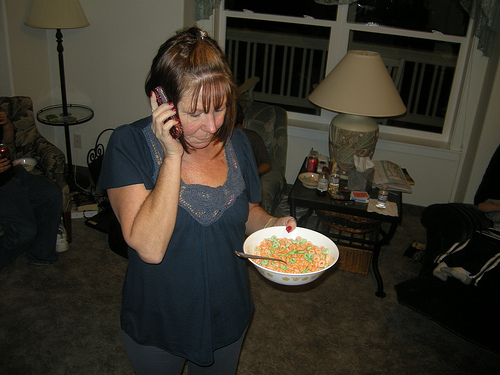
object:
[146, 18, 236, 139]
hair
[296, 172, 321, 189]
bowl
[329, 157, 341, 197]
water bottle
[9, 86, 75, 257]
chair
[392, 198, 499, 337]
chair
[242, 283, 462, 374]
carpet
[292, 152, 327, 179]
can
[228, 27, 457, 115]
wooden fence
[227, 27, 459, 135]
white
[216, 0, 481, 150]
window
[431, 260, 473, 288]
white sock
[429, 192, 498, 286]
boy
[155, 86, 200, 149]
phone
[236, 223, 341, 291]
bowl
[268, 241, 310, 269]
cereal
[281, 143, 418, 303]
stand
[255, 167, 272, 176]
arm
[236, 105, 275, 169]
man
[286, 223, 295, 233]
nail polish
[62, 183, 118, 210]
book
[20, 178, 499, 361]
floor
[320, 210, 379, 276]
basket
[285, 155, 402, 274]
table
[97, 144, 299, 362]
shirt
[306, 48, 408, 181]
lamp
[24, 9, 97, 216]
floor lamp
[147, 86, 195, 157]
hand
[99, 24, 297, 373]
woman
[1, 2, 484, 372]
home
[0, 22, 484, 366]
foreground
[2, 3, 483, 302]
background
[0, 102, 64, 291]
person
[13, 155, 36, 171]
cereal